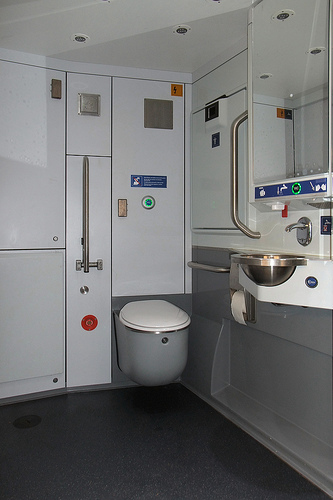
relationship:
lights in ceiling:
[65, 15, 243, 54] [39, 0, 288, 61]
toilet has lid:
[113, 297, 190, 385] [122, 296, 190, 329]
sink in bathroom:
[229, 252, 307, 285] [3, 3, 322, 481]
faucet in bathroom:
[284, 216, 312, 247] [3, 3, 322, 481]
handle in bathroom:
[80, 158, 93, 275] [3, 3, 322, 481]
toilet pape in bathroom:
[226, 286, 248, 326] [19, 58, 331, 497]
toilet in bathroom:
[113, 299, 194, 386] [3, 3, 322, 481]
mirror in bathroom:
[251, 0, 331, 184] [244, 1, 319, 191]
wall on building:
[97, 213, 165, 284] [5, 7, 321, 495]